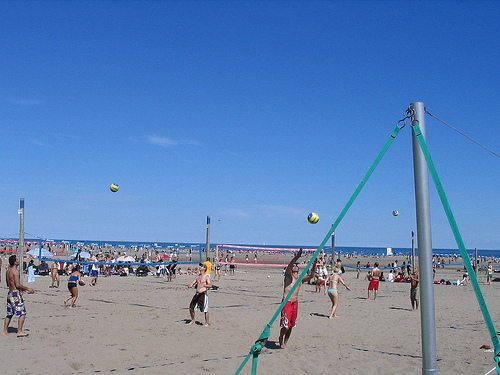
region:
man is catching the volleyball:
[277, 207, 322, 347]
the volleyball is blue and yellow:
[300, 208, 320, 227]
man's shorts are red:
[279, 293, 301, 331]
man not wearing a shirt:
[185, 274, 212, 291]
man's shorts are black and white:
[185, 287, 210, 314]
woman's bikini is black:
[65, 281, 77, 292]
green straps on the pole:
[230, 100, 498, 371]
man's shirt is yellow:
[201, 258, 214, 278]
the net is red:
[212, 241, 320, 266]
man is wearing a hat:
[184, 258, 214, 328]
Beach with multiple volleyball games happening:
[2, 84, 497, 372]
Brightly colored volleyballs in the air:
[81, 168, 406, 235]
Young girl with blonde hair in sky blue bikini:
[322, 258, 347, 344]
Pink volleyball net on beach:
[201, 234, 333, 294]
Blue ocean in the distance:
[1, 200, 498, 262]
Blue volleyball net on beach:
[30, 232, 212, 284]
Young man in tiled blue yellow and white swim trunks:
[1, 245, 41, 347]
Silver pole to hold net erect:
[384, 95, 447, 371]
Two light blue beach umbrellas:
[22, 241, 105, 266]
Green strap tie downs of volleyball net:
[216, 104, 497, 374]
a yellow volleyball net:
[204, 230, 340, 280]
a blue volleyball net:
[12, 229, 223, 296]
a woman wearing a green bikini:
[313, 260, 351, 318]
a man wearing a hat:
[174, 255, 221, 307]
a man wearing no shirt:
[6, 250, 38, 295]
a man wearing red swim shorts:
[278, 249, 312, 344]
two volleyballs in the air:
[92, 175, 337, 227]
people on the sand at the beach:
[66, 242, 433, 351]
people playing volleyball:
[12, 193, 297, 365]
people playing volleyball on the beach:
[13, 191, 264, 373]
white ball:
[107, 180, 122, 194]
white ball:
[290, 210, 323, 225]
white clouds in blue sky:
[31, 21, 91, 68]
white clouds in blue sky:
[119, 114, 149, 154]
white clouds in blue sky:
[204, 133, 234, 159]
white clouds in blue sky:
[232, 50, 283, 107]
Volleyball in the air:
[302, 210, 322, 222]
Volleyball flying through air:
[104, 179, 121, 194]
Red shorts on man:
[280, 299, 300, 328]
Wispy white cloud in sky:
[137, 133, 199, 148]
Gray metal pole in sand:
[405, 100, 446, 372]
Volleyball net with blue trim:
[39, 237, 204, 263]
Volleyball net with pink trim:
[211, 243, 324, 268]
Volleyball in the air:
[392, 208, 402, 215]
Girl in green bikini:
[327, 269, 347, 318]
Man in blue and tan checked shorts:
[5, 288, 25, 317]